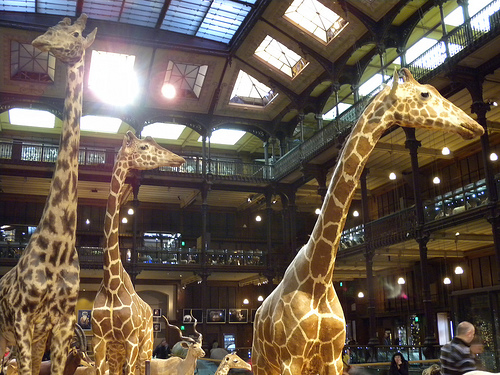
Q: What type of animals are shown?
A: Giraffes.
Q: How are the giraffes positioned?
A: Standing.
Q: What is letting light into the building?
A: Windows.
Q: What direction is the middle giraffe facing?
A: Left.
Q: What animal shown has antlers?
A: Deer.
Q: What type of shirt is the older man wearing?
A: Striped.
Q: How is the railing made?
A: Of metal.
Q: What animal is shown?
A: Giraffe.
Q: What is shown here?
A: Giraffe statues.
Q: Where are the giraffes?
A: Courtyard.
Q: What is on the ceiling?
A: Lights.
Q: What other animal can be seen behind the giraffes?
A: Antelope.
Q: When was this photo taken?
A: Inside, during the daytime.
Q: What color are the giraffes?
A: Brown and yellow.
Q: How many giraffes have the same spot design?
A: Two.